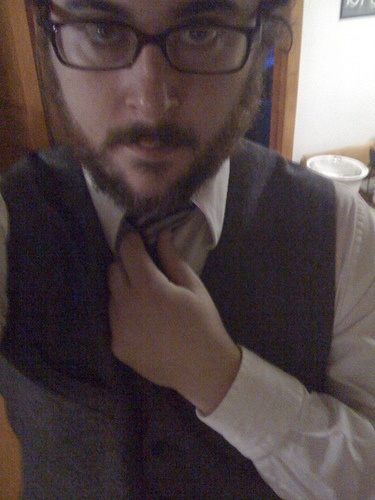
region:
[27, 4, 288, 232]
a man wearing glasses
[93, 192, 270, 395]
a man adjusting his tie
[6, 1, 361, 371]
a man wearing a tie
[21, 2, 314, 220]
man with a brown beard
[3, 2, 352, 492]
man wearing a gray vest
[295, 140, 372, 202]
a white crockpot on table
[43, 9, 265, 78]
a man wearing glasses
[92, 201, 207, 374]
a man touching his tie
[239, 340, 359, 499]
a man wearing a white shirt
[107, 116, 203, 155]
a man with a mustache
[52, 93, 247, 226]
a man with beard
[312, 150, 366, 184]
a white plastic garbage can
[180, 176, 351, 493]
a man wearing a vest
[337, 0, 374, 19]
a picture hanging on a wall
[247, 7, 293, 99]
a man with black hair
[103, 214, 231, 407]
a man's hand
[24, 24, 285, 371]
this is a man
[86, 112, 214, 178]
the mustache is brown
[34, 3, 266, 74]
the glasses are black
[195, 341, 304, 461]
the cuff is white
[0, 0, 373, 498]
the man is wearing a tie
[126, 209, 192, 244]
the knot of a tie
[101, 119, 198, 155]
the mustache is dark brown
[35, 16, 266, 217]
the beard is dark brown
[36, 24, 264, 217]
the mustache and the beard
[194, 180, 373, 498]
the sleeve is white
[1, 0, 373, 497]
the man is dressed and wearing glasses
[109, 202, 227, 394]
the hand touching the tie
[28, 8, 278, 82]
black glasses on the guys face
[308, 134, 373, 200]
white cup on a desk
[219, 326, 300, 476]
white cuff on the guys wrist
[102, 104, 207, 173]
mustache on the guys face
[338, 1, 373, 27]
mirror on the wall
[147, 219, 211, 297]
thumb on the mans hand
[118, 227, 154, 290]
forefinger on the mans hand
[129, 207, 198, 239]
tie on the mans neck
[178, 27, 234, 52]
left eyeball on mans face